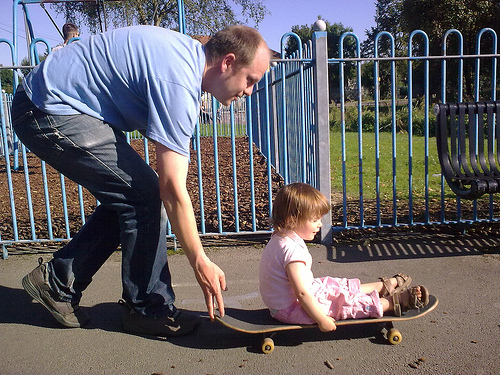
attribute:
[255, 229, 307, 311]
shirt — pink 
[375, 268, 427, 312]
sandals — brown , birkenstock 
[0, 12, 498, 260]
railing — blue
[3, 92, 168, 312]
jeans — blue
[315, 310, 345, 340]
hand — little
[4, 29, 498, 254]
fence — blue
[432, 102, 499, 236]
bench — black 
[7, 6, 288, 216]
tee shirt — blue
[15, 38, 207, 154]
shirt — blue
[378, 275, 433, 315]
shoes — brown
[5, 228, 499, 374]
walkway — paved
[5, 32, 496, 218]
fencing — blue, metal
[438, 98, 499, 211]
bench — black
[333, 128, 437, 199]
area — wood-chipped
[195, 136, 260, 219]
area — grassy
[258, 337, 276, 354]
wheel — yellow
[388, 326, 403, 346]
wheel — yellow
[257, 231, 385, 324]
outfit — pink